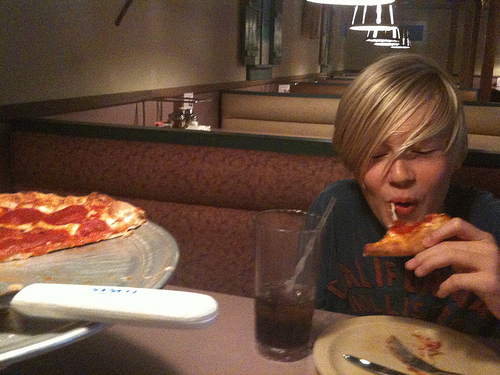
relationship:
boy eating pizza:
[277, 54, 499, 333] [361, 209, 459, 265]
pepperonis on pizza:
[0, 194, 103, 263] [5, 184, 144, 261]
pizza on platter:
[5, 184, 144, 261] [6, 217, 182, 375]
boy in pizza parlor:
[277, 54, 499, 333] [3, 1, 498, 375]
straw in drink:
[291, 195, 341, 287] [250, 203, 324, 366]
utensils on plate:
[343, 323, 477, 373] [318, 308, 488, 375]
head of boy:
[338, 52, 472, 231] [277, 54, 499, 333]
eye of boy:
[411, 145, 442, 162] [277, 54, 499, 333]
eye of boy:
[366, 149, 388, 162] [277, 54, 499, 333]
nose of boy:
[387, 162, 414, 189] [277, 54, 499, 333]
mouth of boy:
[384, 193, 418, 214] [277, 54, 499, 333]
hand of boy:
[406, 214, 500, 312] [277, 54, 499, 333]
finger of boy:
[434, 268, 475, 302] [277, 54, 499, 333]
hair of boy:
[324, 51, 470, 175] [277, 54, 499, 333]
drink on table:
[250, 203, 324, 366] [11, 269, 380, 374]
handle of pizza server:
[21, 276, 213, 331] [1, 274, 223, 336]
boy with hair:
[277, 54, 499, 333] [324, 51, 470, 175]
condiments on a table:
[156, 89, 221, 135] [170, 95, 499, 177]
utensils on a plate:
[343, 323, 477, 373] [318, 308, 488, 375]